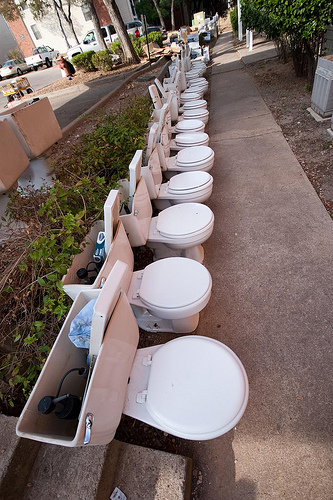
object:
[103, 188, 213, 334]
seat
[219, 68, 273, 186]
sidewalk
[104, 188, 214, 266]
toilet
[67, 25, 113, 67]
car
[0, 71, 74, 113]
street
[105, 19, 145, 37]
truck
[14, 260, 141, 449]
tank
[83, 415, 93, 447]
handle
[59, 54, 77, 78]
hydrant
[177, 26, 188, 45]
sign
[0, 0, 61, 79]
building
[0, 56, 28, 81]
wagon